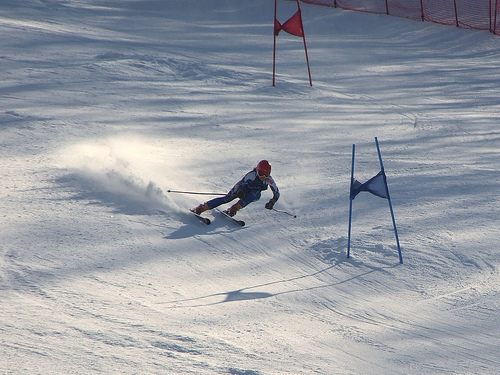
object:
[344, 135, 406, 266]
flag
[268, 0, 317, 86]
flag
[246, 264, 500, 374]
prints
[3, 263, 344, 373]
sunshine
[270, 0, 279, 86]
pole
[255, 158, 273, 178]
helmet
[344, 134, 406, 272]
stand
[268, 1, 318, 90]
stand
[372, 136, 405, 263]
stick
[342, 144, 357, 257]
stick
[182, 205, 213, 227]
skiis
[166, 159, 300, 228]
snow skiing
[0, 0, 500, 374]
snow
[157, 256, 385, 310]
shadow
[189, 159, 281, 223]
man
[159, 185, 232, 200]
pole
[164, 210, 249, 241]
shadow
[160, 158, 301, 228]
course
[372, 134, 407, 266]
pole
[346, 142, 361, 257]
pole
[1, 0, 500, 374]
ice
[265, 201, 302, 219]
pole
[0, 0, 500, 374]
nice view